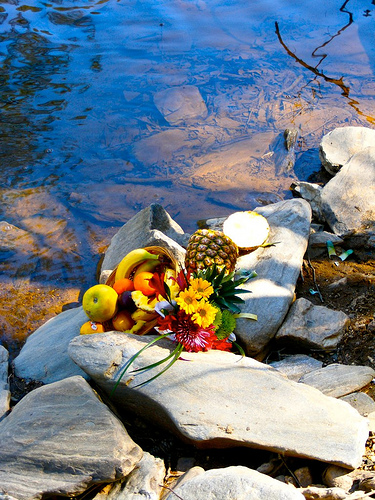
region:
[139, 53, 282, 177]
rocks under the water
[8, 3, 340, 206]
a body of water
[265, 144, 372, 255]
rocks next to the water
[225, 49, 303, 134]
sticks in the water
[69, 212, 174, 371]
a basket of fruit on the rocks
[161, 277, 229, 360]
flowers on the rocks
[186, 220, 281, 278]
a pineapple next to the water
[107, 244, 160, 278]
a banana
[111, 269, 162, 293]
two oranges in the basket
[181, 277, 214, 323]
yellow sun flowers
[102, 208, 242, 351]
fruit next to rocks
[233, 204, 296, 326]
rocks are dark grey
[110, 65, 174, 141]
water is dark blue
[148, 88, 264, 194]
brown rocks in water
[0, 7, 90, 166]
green tree in reflection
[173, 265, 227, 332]
yellow flowers with fruit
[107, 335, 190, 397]
green leaves with flowers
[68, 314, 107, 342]
red and white sticker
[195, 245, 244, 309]
green fronds on pineapple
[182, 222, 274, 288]
sliced pineapple on rocks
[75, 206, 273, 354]
fruits on the rocks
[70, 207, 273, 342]
fruits sitting next to the water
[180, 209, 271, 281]
pineapple next to the other fruits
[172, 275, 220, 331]
flowers next to the fruits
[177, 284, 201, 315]
a flower next to the flowers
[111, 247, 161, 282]
a banana in the basket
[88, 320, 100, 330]
stickers on the fruit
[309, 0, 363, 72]
a shadow reflection in the water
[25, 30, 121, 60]
a ripple of water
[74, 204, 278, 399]
fruits and flowers next to the water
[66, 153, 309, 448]
multiple fruits on rocks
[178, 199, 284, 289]
this is a pineapple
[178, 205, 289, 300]
the pineapple is sliced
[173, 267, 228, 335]
this is a yellow flower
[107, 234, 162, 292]
yellow banana in basket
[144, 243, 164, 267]
green tip on banana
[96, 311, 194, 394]
green foliage on bouqet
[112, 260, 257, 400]
a bouqet of flowers with fruit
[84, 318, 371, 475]
a light grey rock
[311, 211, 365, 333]
debris on ground next to rocks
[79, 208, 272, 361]
pile of fruit on rocks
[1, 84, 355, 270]
rocks under the water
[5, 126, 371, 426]
rocks on the edge of the water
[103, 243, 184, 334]
fruit in a wooden basket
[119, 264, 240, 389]
a bunch of flowers on some rocks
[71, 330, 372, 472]
a large flat rock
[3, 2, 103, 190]
reflection of a tree in the water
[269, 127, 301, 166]
tip of a rock coming out of the water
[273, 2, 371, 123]
reflection of a branch in the water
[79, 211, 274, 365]
fruit and flowers on some rocks